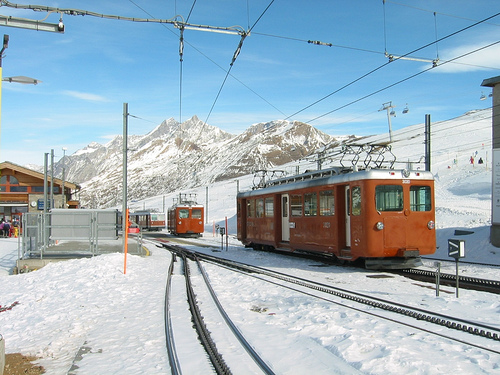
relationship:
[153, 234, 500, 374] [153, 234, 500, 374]
rail has rail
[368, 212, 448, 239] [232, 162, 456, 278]
lights are on front of train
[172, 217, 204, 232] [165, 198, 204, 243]
lights are on front of train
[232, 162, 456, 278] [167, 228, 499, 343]
train on track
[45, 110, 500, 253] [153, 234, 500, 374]
mountain covered in rail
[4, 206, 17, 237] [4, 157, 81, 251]
people are standing by station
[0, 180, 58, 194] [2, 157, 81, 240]
windows are on building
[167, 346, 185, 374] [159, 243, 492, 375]
edge of a rail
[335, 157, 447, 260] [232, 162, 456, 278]
front of a train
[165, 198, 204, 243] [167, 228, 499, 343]
train on track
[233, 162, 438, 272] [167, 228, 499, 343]
train are on track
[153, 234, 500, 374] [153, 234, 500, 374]
rail on top of rail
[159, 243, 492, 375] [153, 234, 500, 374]
rail in rail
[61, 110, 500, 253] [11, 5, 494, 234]
mountain in background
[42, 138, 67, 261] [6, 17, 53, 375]
poles are on side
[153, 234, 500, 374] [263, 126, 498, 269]
rail on hill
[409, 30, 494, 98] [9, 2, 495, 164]
clouds are in sky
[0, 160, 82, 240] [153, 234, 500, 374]
building on rail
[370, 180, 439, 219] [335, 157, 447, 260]
windshield in front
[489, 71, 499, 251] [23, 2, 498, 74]
tower for a ski lift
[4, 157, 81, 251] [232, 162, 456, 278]
station for a train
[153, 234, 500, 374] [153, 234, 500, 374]
rail are on rail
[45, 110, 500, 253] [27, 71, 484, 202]
mountain are in distance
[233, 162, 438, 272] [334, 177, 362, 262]
train has entrance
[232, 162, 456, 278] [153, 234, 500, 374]
train has rail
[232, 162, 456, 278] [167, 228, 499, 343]
train has a track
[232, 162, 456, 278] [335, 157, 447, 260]
train in front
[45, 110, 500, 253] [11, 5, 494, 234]
mountain are in background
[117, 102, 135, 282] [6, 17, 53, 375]
pole to side